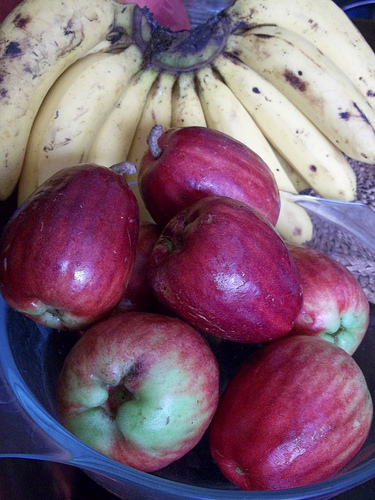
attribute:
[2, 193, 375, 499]
bowl — blue, made of glass, translucent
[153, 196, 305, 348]
piece of fruit — red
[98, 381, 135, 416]
hole — small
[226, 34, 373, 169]
banana — yellow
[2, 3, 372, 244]
bananas — yellow, grouped together, in a bushel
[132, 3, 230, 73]
stem — brown, thick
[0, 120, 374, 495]
apples — red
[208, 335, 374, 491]
apple — juicy, sweet, red, shiny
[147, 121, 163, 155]
stem — gnarled, woody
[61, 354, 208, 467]
marks — green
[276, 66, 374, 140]
marks — black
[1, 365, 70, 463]
handle — made of glass